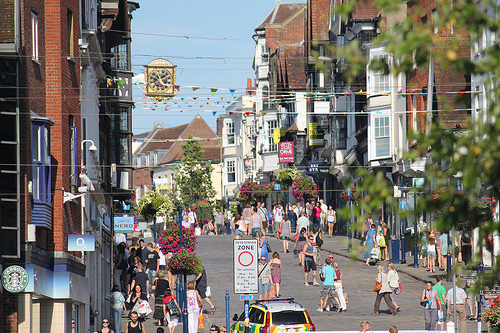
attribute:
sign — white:
[230, 236, 265, 301]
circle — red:
[235, 249, 255, 274]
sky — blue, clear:
[167, 11, 252, 47]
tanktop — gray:
[301, 242, 320, 263]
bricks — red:
[47, 14, 58, 48]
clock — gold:
[141, 53, 179, 102]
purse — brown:
[370, 281, 382, 294]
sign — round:
[2, 256, 30, 304]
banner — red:
[277, 141, 297, 163]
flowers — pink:
[293, 181, 319, 201]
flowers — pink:
[158, 231, 195, 254]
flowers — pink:
[238, 181, 275, 197]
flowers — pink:
[167, 256, 203, 273]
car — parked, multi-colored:
[218, 295, 324, 331]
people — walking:
[318, 253, 406, 314]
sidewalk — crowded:
[301, 225, 399, 258]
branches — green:
[401, 129, 500, 221]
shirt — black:
[144, 250, 160, 271]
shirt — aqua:
[318, 261, 338, 287]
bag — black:
[162, 299, 183, 315]